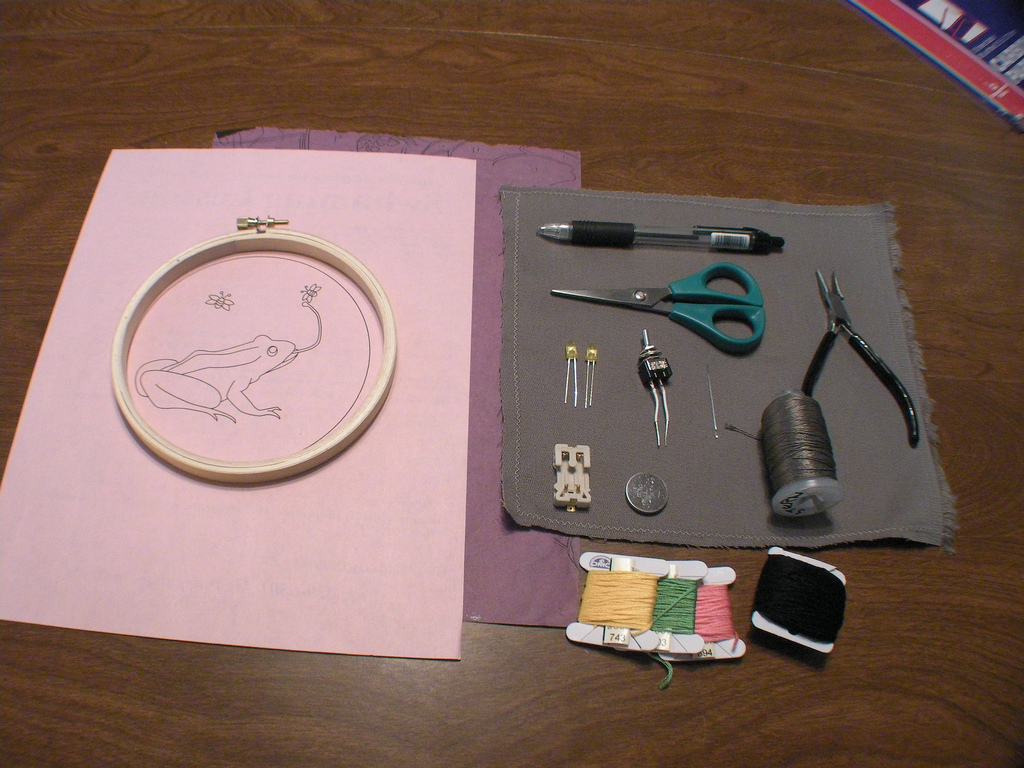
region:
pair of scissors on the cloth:
[548, 266, 767, 346]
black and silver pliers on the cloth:
[791, 260, 919, 451]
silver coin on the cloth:
[624, 475, 664, 514]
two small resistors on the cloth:
[555, 339, 600, 412]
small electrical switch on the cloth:
[633, 326, 671, 444]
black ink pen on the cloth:
[539, 216, 783, 259]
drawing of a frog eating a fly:
[121, 250, 374, 469]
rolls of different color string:
[564, 550, 746, 681]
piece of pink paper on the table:
[0, 145, 476, 665]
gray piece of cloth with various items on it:
[492, 193, 938, 552]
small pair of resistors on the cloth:
[557, 341, 602, 415]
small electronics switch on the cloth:
[631, 329, 674, 444]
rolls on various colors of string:
[560, 543, 852, 680]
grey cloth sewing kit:
[497, 181, 960, 543]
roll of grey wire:
[753, 390, 837, 511]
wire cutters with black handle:
[797, 269, 915, 443]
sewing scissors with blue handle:
[551, 259, 767, 349]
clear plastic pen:
[537, 218, 784, 251]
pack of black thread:
[753, 548, 846, 653]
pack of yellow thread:
[566, 551, 661, 650]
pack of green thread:
[652, 548, 706, 653]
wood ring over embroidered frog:
[111, 232, 396, 483]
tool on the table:
[538, 195, 734, 260]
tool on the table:
[542, 271, 762, 328]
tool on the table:
[557, 335, 577, 409]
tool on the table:
[583, 338, 612, 405]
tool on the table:
[624, 325, 685, 431]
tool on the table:
[784, 253, 947, 431]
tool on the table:
[536, 426, 601, 519]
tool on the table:
[593, 593, 657, 669]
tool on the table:
[538, 220, 782, 268]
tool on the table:
[545, 265, 758, 339]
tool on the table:
[585, 344, 608, 408]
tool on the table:
[560, 326, 580, 418]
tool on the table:
[545, 436, 603, 520]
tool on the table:
[612, 462, 669, 527]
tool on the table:
[618, 319, 675, 468]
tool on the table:
[750, 386, 840, 508]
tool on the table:
[794, 268, 928, 427]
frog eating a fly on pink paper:
[117, 281, 329, 436]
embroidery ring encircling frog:
[104, 212, 405, 491]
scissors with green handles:
[540, 256, 774, 362]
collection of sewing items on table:
[0, 120, 967, 687]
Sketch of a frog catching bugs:
[132, 282, 325, 423]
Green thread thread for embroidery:
[653, 559, 705, 690]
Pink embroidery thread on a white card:
[697, 566, 745, 661]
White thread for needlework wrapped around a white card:
[748, 544, 848, 658]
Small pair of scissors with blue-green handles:
[549, 260, 765, 353]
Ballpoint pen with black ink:
[536, 216, 784, 256]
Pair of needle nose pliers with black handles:
[803, 272, 918, 447]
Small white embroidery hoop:
[107, 215, 392, 482]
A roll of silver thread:
[759, 393, 842, 520]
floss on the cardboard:
[748, 531, 857, 645]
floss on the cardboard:
[566, 524, 623, 658]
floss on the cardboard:
[656, 533, 680, 673]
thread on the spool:
[704, 386, 930, 539]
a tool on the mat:
[817, 283, 923, 519]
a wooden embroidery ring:
[149, 215, 383, 484]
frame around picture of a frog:
[103, 181, 407, 495]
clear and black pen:
[524, 196, 800, 263]